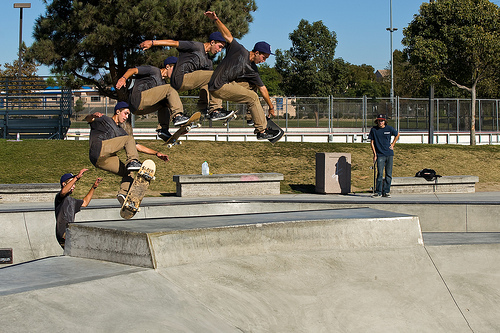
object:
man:
[366, 113, 400, 198]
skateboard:
[370, 149, 380, 194]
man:
[52, 166, 101, 250]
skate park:
[0, 172, 499, 332]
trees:
[17, 0, 259, 121]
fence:
[0, 90, 498, 147]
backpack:
[412, 167, 440, 183]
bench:
[373, 176, 478, 194]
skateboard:
[118, 157, 158, 221]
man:
[202, 9, 277, 141]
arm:
[213, 17, 243, 53]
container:
[199, 160, 211, 175]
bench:
[172, 171, 284, 198]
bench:
[0, 182, 74, 204]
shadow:
[332, 154, 352, 195]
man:
[137, 32, 234, 123]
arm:
[151, 38, 196, 48]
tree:
[286, 20, 354, 127]